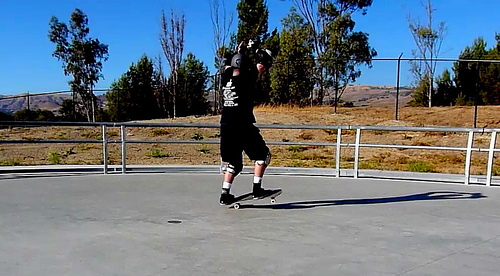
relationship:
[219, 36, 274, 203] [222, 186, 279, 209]
person on a skateboard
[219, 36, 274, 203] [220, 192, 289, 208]
person on a board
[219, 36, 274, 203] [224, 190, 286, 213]
person on a board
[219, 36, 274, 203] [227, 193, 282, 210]
person on a board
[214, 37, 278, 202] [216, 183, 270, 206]
person wearing shoes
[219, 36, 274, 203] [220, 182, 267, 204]
person wearing shoes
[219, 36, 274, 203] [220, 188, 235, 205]
person wearing black shoe